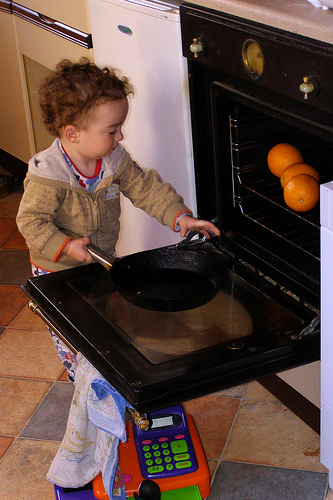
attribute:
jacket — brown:
[14, 138, 179, 241]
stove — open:
[36, 103, 329, 402]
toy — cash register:
[97, 402, 217, 499]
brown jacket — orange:
[38, 171, 118, 244]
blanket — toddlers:
[45, 351, 134, 498]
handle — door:
[25, 299, 152, 430]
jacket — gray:
[12, 134, 192, 274]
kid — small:
[29, 57, 207, 271]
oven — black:
[25, 10, 325, 414]